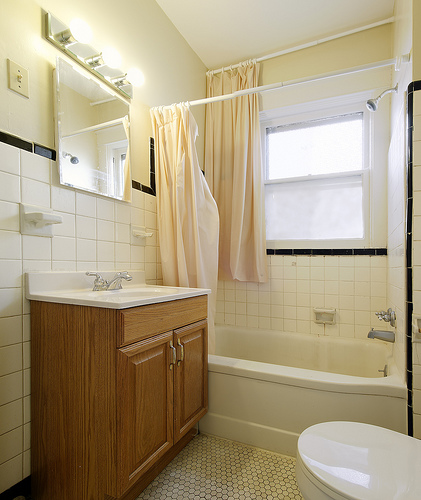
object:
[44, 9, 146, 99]
lights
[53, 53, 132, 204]
mirror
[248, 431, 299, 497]
hexagonal tiles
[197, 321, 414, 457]
bathtub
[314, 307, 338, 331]
soap dish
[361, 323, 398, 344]
faucet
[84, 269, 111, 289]
faucet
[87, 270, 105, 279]
handles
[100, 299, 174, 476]
cabinet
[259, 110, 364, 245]
window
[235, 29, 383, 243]
wall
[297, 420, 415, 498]
set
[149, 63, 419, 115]
rod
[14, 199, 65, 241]
holder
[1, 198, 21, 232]
tile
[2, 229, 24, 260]
tile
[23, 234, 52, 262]
tile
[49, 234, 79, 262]
tile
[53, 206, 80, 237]
tile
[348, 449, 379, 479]
white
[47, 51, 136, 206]
mirror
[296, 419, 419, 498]
lid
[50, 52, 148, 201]
cabinet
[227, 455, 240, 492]
tile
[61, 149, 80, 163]
shower head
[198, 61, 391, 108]
pole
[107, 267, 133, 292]
faucet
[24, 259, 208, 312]
sink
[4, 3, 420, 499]
bathroom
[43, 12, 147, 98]
fixture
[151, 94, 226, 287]
curtain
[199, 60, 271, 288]
curtain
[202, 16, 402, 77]
rod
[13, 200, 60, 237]
soap dish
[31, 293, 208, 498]
brown cabinets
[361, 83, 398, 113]
shower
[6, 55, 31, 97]
switch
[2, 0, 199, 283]
wall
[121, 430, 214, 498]
floor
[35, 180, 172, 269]
wall